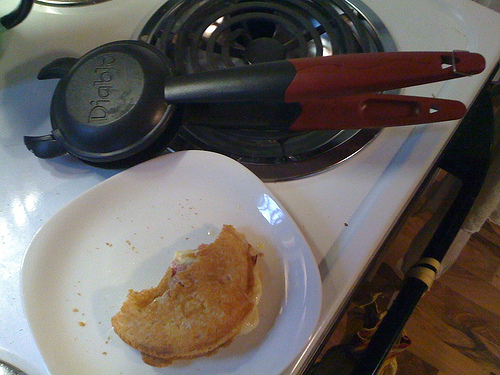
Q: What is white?
A: Plate.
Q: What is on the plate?
A: Food.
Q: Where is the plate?
A: On a stove.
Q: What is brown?
A: Food on plate.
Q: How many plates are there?
A: One.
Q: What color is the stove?
A: White.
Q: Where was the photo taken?
A: In a kitchen.